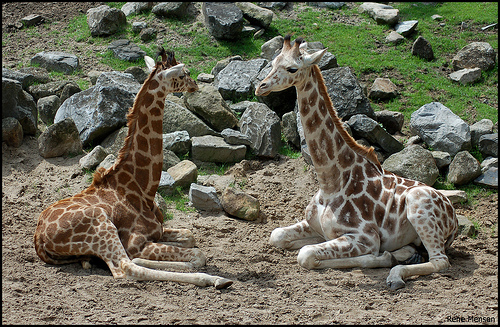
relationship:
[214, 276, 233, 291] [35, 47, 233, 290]
hoof on giraffe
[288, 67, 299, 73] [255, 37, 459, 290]
eye on giraffe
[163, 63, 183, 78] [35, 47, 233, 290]
ear on giraffe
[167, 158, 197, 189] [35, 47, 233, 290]
rock behind giraffe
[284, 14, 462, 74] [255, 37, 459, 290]
grass behind giraffe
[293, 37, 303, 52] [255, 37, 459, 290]
horn on giraffe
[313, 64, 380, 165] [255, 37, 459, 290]
mane on giraffe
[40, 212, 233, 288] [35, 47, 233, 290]
leg on giraffe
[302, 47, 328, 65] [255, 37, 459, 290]
ear on giraffe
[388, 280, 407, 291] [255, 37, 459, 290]
hoof on giraffe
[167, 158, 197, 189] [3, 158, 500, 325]
rock on ground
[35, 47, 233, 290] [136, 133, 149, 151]
giraffe has spot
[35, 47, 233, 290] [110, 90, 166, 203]
giraffe has neck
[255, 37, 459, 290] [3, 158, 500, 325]
giraffe on ground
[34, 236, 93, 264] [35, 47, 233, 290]
tail on giraffe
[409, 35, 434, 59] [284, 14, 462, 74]
rock on grass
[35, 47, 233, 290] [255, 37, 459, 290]
giraffe next to giraffe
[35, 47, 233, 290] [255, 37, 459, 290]
giraffe facing giraffe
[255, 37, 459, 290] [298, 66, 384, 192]
giraffe has neck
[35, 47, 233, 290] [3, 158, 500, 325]
giraffe on ground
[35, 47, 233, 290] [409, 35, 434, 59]
giraffe facing rock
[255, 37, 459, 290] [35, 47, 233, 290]
giraffe facing giraffe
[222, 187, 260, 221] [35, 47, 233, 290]
rock by giraffe